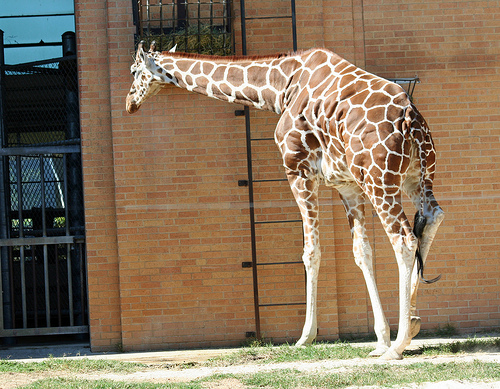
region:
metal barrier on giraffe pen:
[0, 139, 97, 346]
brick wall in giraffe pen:
[88, 0, 486, 324]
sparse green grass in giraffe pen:
[3, 343, 495, 385]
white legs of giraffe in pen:
[289, 236, 451, 372]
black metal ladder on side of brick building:
[225, 0, 330, 344]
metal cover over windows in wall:
[122, 0, 244, 67]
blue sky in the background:
[0, 0, 75, 70]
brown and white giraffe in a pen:
[116, 32, 453, 369]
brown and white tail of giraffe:
[386, 96, 432, 286]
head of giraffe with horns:
[120, 34, 179, 117]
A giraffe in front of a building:
[111, 33, 461, 361]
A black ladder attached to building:
[229, 114, 273, 340]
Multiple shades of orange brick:
[117, 163, 197, 241]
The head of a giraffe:
[120, 41, 192, 119]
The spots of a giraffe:
[296, 54, 333, 169]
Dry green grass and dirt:
[261, 355, 341, 384]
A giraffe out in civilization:
[72, 37, 491, 362]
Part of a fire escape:
[135, 1, 303, 48]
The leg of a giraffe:
[278, 143, 332, 347]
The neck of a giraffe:
[178, 48, 281, 121]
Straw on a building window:
[191, 31, 197, 49]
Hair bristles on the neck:
[206, 57, 268, 61]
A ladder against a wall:
[238, 175, 263, 225]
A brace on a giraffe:
[388, 77, 418, 105]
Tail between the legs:
[414, 211, 424, 238]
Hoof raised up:
[413, 318, 419, 331]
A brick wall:
[157, 143, 227, 178]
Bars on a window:
[145, 5, 179, 20]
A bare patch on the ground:
[307, 360, 341, 370]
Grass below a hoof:
[295, 345, 315, 355]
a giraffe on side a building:
[108, 30, 459, 367]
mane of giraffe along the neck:
[161, 43, 297, 63]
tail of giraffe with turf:
[403, 112, 443, 293]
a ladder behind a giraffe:
[236, 0, 327, 355]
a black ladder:
[228, 3, 328, 351]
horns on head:
[115, 32, 187, 116]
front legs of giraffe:
[277, 173, 394, 358]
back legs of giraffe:
[388, 183, 446, 368]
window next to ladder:
[125, 0, 298, 74]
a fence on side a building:
[6, 36, 126, 354]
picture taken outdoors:
[21, 21, 443, 381]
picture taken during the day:
[18, 28, 400, 380]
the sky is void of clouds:
[13, 11, 43, 34]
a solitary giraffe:
[107, 41, 499, 362]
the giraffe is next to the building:
[93, 53, 499, 348]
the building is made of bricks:
[92, 88, 163, 252]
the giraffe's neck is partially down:
[114, 47, 289, 124]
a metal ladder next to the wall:
[238, 76, 390, 386]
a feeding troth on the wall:
[140, 35, 234, 52]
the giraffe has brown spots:
[318, 73, 411, 186]